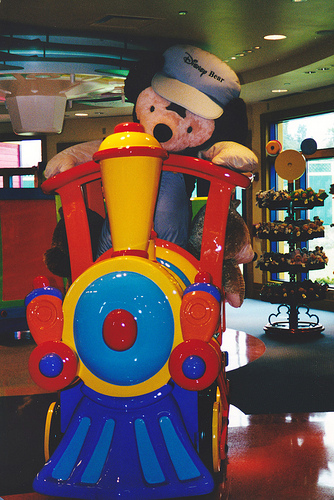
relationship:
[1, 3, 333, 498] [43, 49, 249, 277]
scene shows toy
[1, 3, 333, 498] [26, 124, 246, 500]
scene shows toy train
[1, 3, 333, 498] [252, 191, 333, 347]
scene shows rack of toys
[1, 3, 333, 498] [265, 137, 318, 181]
scene shows mickey mouse head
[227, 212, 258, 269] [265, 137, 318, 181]
bear head same direction as mickey mouse head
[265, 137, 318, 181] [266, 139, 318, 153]
mickey mouse head has famous mouse ears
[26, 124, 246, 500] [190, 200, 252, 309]
toy train has bear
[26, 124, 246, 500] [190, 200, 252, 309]
toy train shows bear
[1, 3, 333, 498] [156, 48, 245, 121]
scene shows hat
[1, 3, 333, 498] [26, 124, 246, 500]
scene includes toy train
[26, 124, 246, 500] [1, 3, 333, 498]
toy train a part of scene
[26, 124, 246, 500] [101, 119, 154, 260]
toy train has smoke stack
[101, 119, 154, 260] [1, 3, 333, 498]
smoke stack part of scene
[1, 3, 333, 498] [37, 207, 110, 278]
scene features a teddy bear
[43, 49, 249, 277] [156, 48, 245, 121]
toy wearing a cap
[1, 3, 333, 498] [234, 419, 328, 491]
scene shows a floor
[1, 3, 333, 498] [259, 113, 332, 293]
scene shows a window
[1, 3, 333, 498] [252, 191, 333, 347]
scene has a stand with bears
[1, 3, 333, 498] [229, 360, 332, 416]
scene has a rug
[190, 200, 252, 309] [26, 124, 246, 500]
bear are on toy train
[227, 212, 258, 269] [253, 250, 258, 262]
bear head has a nose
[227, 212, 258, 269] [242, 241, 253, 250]
bear head has eye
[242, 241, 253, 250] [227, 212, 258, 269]
eye one of two on bear head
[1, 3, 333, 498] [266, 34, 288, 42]
scene shows a light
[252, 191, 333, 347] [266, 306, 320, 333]
rack of toys has design on base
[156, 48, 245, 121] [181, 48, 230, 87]
hat reads disney bear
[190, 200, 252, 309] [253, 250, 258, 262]
bear has a nose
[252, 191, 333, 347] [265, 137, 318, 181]
rack of toys features mickey mouse head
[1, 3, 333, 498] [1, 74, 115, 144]
scene shows center chandalier